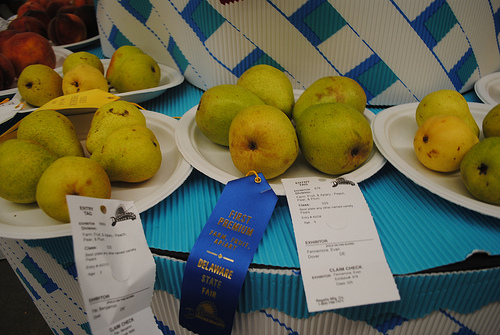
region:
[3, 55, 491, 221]
Four plates of pears on a table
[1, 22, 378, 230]
Three plates with 5 pears on the table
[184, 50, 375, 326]
Plate of pears with blue ribbon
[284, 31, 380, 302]
Plate of pears with entry tag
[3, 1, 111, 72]
2 plates with peaches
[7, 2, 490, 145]
Pears and peaches on white plates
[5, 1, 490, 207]
Pears and peaches on plates on a table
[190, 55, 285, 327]
First premium blue ribbon on a plate with pears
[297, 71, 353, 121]
Light bruising on a pear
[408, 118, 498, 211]
yellow and green pear on a plate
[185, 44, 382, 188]
Five pears arranged in star shape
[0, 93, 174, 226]
Five pears sitting on top of a paper plate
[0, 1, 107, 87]
Apples sitting on paper plates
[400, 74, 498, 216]
Four pears arranged on plate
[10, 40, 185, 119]
Five pears in state fair show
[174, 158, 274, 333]
Award for state fair pears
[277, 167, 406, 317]
Paper tag attached to plate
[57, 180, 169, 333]
Paper entry tag for pear showing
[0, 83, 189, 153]
Yellow award tage on top of pears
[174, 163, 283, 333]
Blue first premium tag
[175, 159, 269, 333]
the tag is blue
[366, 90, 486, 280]
the plate is white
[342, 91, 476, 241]
the plate is white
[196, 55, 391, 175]
pairs on a plate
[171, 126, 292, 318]
a blue ribbon near some pairs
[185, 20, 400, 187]
five green pairs on a plate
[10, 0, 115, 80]
red peaches on a plate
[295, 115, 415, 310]
a white receipt near some pairs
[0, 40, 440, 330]
green pairs on a table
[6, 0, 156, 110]
peaches and pairs on a table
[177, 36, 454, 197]
a white plate with pairs on it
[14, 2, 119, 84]
a white plate with peaches on it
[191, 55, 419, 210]
pairs sitting on a plate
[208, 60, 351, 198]
Pears on a plate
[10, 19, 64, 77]
peaches on a plate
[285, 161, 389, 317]
tag on a plate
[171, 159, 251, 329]
blue tag on a plate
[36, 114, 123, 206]
fan pears on a plate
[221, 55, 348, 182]
green pears on a plate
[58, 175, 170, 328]
Tag on a plate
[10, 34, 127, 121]
Peaches on a table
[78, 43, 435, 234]
Pears on a table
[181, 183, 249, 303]
Delaware state fair tag